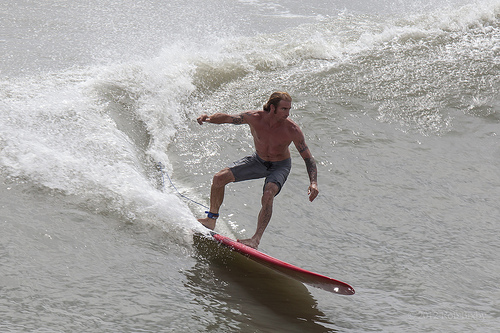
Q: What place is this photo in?
A: It is at the ocean.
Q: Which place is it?
A: It is an ocean.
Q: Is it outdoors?
A: Yes, it is outdoors.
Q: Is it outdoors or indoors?
A: It is outdoors.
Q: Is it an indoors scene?
A: No, it is outdoors.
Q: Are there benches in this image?
A: No, there are no benches.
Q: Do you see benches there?
A: No, there are no benches.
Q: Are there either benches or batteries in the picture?
A: No, there are no benches or batteries.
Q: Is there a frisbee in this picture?
A: No, there are no frisbees.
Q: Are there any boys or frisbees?
A: No, there are no frisbees or boys.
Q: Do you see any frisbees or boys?
A: No, there are no frisbees or boys.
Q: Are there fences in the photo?
A: No, there are no fences.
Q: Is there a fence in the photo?
A: No, there are no fences.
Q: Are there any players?
A: No, there are no players.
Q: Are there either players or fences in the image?
A: No, there are no players or fences.